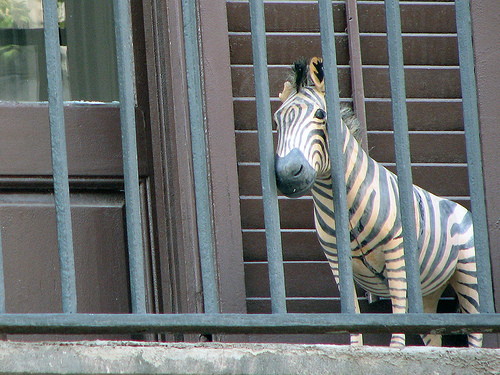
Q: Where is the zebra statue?
A: A porch.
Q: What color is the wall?
A: Brown.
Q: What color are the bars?
A: Black.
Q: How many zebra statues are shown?
A: One.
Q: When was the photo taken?
A: Daytime.